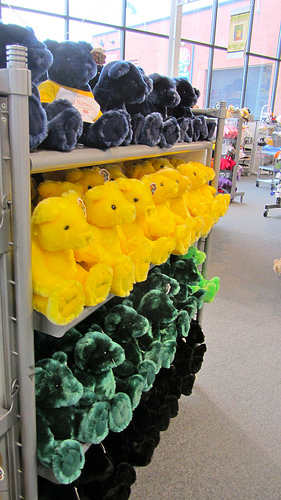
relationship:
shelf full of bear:
[0, 40, 215, 499] [37, 38, 127, 147]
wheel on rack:
[261, 209, 269, 220] [216, 105, 254, 210]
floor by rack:
[132, 170, 277, 500] [216, 105, 254, 210]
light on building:
[103, 34, 118, 47] [80, 1, 280, 148]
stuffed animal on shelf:
[102, 300, 156, 403] [0, 40, 215, 499]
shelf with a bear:
[0, 40, 215, 499] [37, 38, 127, 147]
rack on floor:
[216, 105, 254, 210] [132, 170, 277, 500]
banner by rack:
[224, 6, 255, 55] [216, 105, 254, 210]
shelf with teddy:
[0, 40, 215, 499] [81, 182, 150, 300]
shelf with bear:
[0, 40, 215, 499] [37, 38, 127, 147]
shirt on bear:
[37, 79, 105, 123] [37, 38, 127, 147]